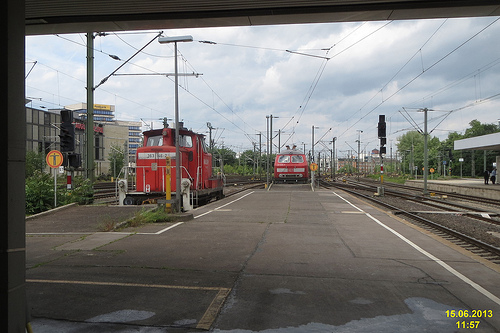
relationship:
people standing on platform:
[468, 161, 498, 189] [404, 176, 498, 201]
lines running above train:
[25, 20, 497, 145] [130, 125, 225, 210]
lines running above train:
[25, 20, 497, 145] [271, 149, 309, 185]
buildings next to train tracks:
[24, 86, 158, 217] [71, 176, 131, 200]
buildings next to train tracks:
[24, 86, 158, 217] [216, 169, 266, 186]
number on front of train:
[137, 150, 177, 160] [119, 122, 224, 211]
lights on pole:
[56, 107, 77, 157] [63, 152, 72, 202]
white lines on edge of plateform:
[326, 182, 499, 327] [151, 180, 493, 331]